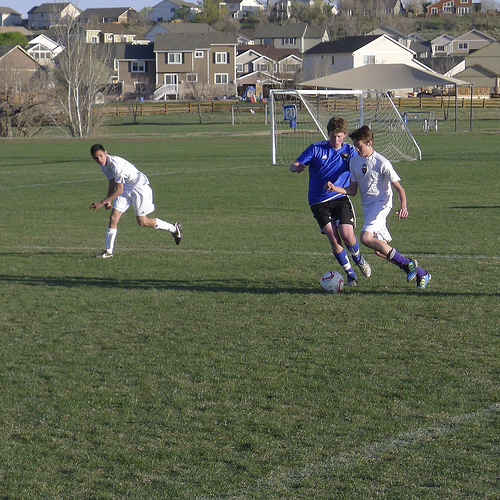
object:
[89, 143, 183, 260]
children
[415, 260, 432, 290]
shoes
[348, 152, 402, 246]
white uniform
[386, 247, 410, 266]
socks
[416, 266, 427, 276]
socks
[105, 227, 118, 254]
white socks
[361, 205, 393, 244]
shorts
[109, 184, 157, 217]
shorts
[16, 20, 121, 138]
tree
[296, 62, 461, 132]
awning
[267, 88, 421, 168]
goal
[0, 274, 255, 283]
shadows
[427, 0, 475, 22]
house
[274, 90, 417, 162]
mesh cage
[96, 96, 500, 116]
fence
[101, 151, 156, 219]
uniform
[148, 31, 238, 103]
home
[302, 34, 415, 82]
home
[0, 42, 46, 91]
home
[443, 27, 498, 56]
home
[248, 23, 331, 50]
home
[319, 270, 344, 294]
ball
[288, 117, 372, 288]
boy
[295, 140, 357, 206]
t-shirt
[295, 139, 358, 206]
jersey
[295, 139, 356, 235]
uniform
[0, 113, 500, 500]
grass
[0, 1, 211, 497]
left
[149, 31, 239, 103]
house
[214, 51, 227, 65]
windows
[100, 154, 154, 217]
white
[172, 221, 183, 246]
cleats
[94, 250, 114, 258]
cleats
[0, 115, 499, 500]
field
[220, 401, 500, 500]
line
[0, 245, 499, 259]
line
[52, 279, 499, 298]
shadows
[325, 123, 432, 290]
player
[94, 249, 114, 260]
left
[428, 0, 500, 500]
right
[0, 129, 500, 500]
center